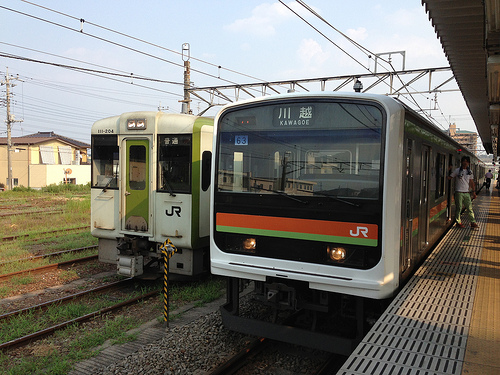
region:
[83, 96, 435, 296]
two trains on the tracks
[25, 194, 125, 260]
grass on the train tracks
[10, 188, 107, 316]
green grass on the tracks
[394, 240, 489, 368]
platform near a train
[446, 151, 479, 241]
person getting off train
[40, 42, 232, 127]
clear sky of blue above trains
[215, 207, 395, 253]
orange and green stripe on train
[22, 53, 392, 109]
lines above trains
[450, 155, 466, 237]
man wearing green pants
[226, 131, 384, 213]
windshield wipers on a train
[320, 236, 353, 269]
left headlight on train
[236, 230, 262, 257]
right headlight on train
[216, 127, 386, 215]
front window of train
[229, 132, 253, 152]
number 63 on train window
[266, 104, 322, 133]
sign on front of train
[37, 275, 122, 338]
train tracks in a grassy area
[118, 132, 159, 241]
door on front of train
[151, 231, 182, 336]
metal and orange pole betwen tracks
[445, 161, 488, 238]
person standing neck to train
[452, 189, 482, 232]
person in green pants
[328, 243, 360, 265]
a headlight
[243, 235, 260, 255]
a headlight on the train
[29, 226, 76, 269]
the train tracks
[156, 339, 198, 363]
small rocks on the ground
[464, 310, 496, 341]
the sidewalk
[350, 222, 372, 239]
a logo on the train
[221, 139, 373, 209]
windshield on the train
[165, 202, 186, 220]
a logo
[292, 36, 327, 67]
a white cloud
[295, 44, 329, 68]
a cloud in the sky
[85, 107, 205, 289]
a green and white train car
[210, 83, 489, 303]
a white, black, red, and green train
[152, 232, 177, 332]
a black and yellow pole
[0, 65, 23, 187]
a metal power pole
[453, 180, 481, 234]
green pants on a man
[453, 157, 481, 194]
a white t shirt on a man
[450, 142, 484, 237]
a man getting out of a train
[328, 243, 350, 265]
a train head light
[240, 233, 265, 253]
a train head light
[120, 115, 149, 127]
a train light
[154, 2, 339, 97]
The sky is blue and cloudy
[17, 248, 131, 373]
The grass is patchy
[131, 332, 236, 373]
The gravel is near the tracks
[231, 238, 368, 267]
The lights are on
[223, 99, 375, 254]
The front of the bus is shiny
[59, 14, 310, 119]
The power lines are above the trains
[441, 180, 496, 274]
The ground has shadows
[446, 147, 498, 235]
The person is standing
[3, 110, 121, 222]
The building is in the back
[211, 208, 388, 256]
The front of the train is orange and green